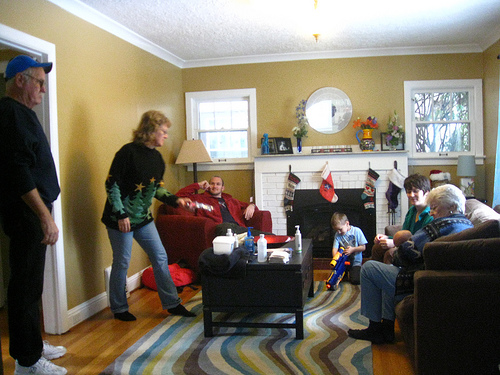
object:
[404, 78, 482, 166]
window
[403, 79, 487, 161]
frame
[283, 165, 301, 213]
stockings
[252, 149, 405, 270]
fireplace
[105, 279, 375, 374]
carpet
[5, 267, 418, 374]
floor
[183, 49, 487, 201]
wall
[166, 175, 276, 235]
man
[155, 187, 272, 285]
chair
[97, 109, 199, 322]
woman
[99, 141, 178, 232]
christmas sweater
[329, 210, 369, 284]
boy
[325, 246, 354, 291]
toy gun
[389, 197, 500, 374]
couch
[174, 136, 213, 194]
lamp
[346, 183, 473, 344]
woman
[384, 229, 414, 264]
baby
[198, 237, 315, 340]
table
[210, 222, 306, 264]
gifts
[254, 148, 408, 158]
mantel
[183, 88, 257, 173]
window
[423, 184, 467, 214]
blonde hair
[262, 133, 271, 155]
knick knacks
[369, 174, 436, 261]
woman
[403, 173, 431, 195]
short hair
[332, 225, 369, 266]
blue shirt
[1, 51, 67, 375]
man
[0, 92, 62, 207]
black shirt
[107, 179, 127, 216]
christmas tree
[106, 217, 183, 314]
jeans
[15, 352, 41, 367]
black socks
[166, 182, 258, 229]
red jacket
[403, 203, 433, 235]
green shirt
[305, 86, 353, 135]
window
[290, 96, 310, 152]
items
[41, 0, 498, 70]
ceiling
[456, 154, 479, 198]
stand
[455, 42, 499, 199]
corner